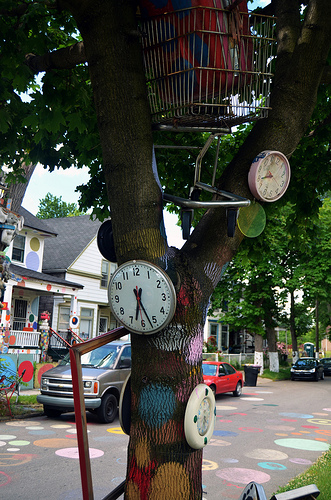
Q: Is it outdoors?
A: Yes, it is outdoors.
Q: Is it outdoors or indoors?
A: It is outdoors.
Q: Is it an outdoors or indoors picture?
A: It is outdoors.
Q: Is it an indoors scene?
A: No, it is outdoors.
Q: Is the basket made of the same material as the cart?
A: Yes, both the basket and the cart are made of metal.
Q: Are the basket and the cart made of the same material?
A: Yes, both the basket and the cart are made of metal.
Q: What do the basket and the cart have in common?
A: The material, both the basket and the cart are metallic.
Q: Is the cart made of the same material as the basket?
A: Yes, both the cart and the basket are made of metal.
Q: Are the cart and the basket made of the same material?
A: Yes, both the cart and the basket are made of metal.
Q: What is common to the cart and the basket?
A: The material, both the cart and the basket are metallic.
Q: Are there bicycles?
A: No, there are no bicycles.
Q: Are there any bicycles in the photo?
A: No, there are no bicycles.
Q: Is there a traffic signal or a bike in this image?
A: No, there are no bikes or traffic lights.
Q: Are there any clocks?
A: Yes, there is a clock.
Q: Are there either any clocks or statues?
A: Yes, there is a clock.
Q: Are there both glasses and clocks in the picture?
A: No, there is a clock but no glasses.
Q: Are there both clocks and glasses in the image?
A: No, there is a clock but no glasses.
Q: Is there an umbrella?
A: No, there are no umbrellas.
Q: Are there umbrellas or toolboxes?
A: No, there are no umbrellas or toolboxes.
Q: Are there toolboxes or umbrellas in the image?
A: No, there are no umbrellas or toolboxes.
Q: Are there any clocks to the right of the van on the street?
A: Yes, there is a clock to the right of the van.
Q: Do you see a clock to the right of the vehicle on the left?
A: Yes, there is a clock to the right of the van.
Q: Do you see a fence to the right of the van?
A: No, there is a clock to the right of the van.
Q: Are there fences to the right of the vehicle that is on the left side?
A: No, there is a clock to the right of the van.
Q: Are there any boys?
A: No, there are no boys.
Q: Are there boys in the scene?
A: No, there are no boys.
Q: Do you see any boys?
A: No, there are no boys.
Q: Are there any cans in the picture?
A: Yes, there is a can.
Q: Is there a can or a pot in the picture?
A: Yes, there is a can.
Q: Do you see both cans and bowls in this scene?
A: No, there is a can but no bowls.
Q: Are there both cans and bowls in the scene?
A: No, there is a can but no bowls.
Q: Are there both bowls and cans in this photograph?
A: No, there is a can but no bowls.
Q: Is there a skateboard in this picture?
A: No, there are no skateboards.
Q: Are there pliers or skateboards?
A: No, there are no skateboards or pliers.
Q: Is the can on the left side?
A: No, the can is on the right of the image.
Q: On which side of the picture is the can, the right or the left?
A: The can is on the right of the image.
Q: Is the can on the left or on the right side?
A: The can is on the right of the image.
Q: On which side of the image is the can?
A: The can is on the right of the image.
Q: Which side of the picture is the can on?
A: The can is on the right of the image.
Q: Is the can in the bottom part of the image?
A: Yes, the can is in the bottom of the image.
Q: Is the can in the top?
A: No, the can is in the bottom of the image.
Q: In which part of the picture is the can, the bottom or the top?
A: The can is in the bottom of the image.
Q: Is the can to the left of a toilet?
A: No, the can is to the left of a car.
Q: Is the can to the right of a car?
A: No, the can is to the left of a car.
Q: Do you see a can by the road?
A: Yes, there is a can by the road.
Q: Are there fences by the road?
A: No, there is a can by the road.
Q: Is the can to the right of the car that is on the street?
A: Yes, the can is to the right of the car.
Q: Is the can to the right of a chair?
A: No, the can is to the right of the car.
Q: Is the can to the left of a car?
A: No, the can is to the right of a car.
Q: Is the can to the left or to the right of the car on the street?
A: The can is to the right of the car.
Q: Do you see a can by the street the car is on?
A: Yes, there is a can by the street.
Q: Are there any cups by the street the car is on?
A: No, there is a can by the street.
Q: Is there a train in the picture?
A: No, there are no trains.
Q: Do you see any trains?
A: No, there are no trains.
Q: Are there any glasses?
A: No, there are no glasses.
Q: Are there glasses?
A: No, there are no glasses.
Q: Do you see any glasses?
A: No, there are no glasses.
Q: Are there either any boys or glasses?
A: No, there are no glasses or boys.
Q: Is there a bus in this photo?
A: No, there are no buses.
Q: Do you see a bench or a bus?
A: No, there are no buses or benches.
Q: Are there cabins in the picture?
A: No, there are no cabins.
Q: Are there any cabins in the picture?
A: No, there are no cabins.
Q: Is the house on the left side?
A: Yes, the house is on the left of the image.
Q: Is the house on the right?
A: No, the house is on the left of the image.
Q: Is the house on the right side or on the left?
A: The house is on the left of the image.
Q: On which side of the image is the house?
A: The house is on the left of the image.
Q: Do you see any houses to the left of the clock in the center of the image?
A: Yes, there is a house to the left of the clock.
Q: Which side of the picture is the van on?
A: The van is on the left of the image.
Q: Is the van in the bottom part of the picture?
A: Yes, the van is in the bottom of the image.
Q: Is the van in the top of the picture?
A: No, the van is in the bottom of the image.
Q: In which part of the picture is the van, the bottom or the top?
A: The van is in the bottom of the image.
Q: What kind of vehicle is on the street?
A: The vehicle is a van.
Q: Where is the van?
A: The van is on the street.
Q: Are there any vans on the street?
A: Yes, there is a van on the street.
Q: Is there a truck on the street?
A: No, there is a van on the street.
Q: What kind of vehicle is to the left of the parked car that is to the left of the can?
A: The vehicle is a van.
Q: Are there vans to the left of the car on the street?
A: Yes, there is a van to the left of the car.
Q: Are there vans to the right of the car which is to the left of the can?
A: No, the van is to the left of the car.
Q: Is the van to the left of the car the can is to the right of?
A: Yes, the van is to the left of the car.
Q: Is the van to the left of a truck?
A: No, the van is to the left of the car.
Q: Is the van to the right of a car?
A: No, the van is to the left of a car.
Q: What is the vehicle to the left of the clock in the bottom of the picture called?
A: The vehicle is a van.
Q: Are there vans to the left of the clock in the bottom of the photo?
A: Yes, there is a van to the left of the clock.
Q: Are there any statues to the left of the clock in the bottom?
A: No, there is a van to the left of the clock.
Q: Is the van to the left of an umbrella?
A: No, the van is to the left of the clock.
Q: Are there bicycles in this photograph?
A: No, there are no bicycles.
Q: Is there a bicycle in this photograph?
A: No, there are no bicycles.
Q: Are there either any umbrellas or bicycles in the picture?
A: No, there are no bicycles or umbrellas.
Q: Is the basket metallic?
A: Yes, the basket is metallic.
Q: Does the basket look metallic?
A: Yes, the basket is metallic.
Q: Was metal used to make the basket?
A: Yes, the basket is made of metal.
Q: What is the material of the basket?
A: The basket is made of metal.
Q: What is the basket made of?
A: The basket is made of metal.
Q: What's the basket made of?
A: The basket is made of metal.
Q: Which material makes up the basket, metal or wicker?
A: The basket is made of metal.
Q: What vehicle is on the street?
A: The vehicle is a car.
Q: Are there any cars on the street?
A: Yes, there is a car on the street.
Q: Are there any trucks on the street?
A: No, there is a car on the street.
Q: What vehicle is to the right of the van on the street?
A: The vehicle is a car.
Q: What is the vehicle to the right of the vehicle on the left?
A: The vehicle is a car.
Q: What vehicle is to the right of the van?
A: The vehicle is a car.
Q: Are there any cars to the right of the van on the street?
A: Yes, there is a car to the right of the van.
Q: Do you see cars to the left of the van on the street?
A: No, the car is to the right of the van.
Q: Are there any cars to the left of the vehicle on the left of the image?
A: No, the car is to the right of the van.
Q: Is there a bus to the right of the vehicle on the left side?
A: No, there is a car to the right of the van.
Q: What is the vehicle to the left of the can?
A: The vehicle is a car.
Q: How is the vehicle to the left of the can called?
A: The vehicle is a car.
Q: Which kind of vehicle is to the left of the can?
A: The vehicle is a car.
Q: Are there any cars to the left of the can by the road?
A: Yes, there is a car to the left of the can.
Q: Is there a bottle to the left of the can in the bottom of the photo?
A: No, there is a car to the left of the can.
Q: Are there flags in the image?
A: No, there are no flags.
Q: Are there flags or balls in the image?
A: No, there are no flags or balls.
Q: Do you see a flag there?
A: No, there are no flags.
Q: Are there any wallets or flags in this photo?
A: No, there are no flags or wallets.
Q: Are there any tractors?
A: No, there are no tractors.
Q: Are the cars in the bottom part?
A: Yes, the cars are in the bottom of the image.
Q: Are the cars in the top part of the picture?
A: No, the cars are in the bottom of the image.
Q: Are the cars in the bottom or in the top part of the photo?
A: The cars are in the bottom of the image.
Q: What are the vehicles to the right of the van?
A: The vehicles are cars.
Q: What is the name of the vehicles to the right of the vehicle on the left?
A: The vehicles are cars.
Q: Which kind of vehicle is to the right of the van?
A: The vehicles are cars.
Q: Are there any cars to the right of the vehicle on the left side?
A: Yes, there are cars to the right of the van.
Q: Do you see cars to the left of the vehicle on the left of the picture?
A: No, the cars are to the right of the van.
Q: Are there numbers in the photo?
A: Yes, there are numbers.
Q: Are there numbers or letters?
A: Yes, there are numbers.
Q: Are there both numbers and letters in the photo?
A: No, there are numbers but no letters.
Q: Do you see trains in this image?
A: No, there are no trains.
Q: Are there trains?
A: No, there are no trains.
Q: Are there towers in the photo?
A: No, there are no towers.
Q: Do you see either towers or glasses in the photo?
A: No, there are no towers or glasses.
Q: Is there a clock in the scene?
A: Yes, there is a clock.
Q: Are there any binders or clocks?
A: Yes, there is a clock.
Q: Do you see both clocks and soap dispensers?
A: No, there is a clock but no soap dispensers.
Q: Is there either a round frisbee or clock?
A: Yes, there is a round clock.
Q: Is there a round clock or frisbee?
A: Yes, there is a round clock.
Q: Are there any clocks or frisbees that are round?
A: Yes, the clock is round.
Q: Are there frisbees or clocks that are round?
A: Yes, the clock is round.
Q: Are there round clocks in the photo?
A: Yes, there is a round clock.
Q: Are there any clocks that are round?
A: Yes, there is a clock that is round.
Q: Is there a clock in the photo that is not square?
A: Yes, there is a round clock.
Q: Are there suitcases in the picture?
A: No, there are no suitcases.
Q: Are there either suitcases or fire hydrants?
A: No, there are no suitcases or fire hydrants.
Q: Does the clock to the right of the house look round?
A: Yes, the clock is round.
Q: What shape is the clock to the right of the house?
A: The clock is round.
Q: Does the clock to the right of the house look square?
A: No, the clock is round.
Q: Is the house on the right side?
A: No, the house is on the left of the image.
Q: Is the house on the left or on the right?
A: The house is on the left of the image.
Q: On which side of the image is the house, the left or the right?
A: The house is on the left of the image.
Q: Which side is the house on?
A: The house is on the left of the image.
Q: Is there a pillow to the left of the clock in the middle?
A: No, there is a house to the left of the clock.